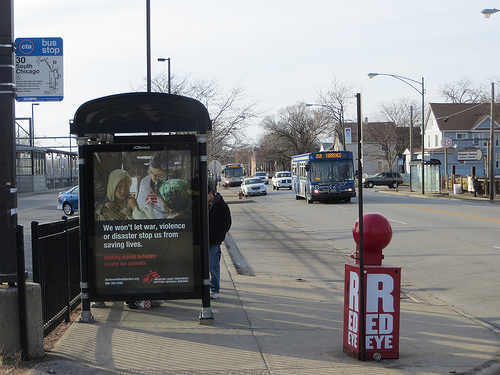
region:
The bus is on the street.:
[278, 135, 415, 240]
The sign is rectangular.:
[9, 27, 70, 114]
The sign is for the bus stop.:
[8, 27, 70, 111]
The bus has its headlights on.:
[284, 130, 374, 217]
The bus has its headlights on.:
[216, 145, 253, 199]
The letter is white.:
[361, 268, 400, 315]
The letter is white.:
[360, 310, 380, 336]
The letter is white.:
[376, 310, 397, 335]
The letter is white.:
[361, 331, 376, 353]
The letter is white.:
[383, 332, 398, 354]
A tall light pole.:
[366, 70, 426, 195]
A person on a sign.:
[96, 165, 133, 216]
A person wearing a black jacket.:
[207, 177, 233, 302]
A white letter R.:
[364, 270, 396, 312]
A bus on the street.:
[289, 148, 358, 206]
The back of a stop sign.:
[208, 155, 225, 192]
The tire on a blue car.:
[61, 199, 74, 216]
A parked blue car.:
[56, 179, 84, 216]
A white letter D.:
[377, 312, 396, 334]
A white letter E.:
[363, 313, 381, 335]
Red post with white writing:
[342, 211, 403, 362]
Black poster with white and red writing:
[74, 133, 214, 303]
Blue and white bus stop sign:
[13, 37, 65, 100]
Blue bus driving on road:
[289, 148, 359, 203]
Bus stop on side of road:
[406, 156, 443, 198]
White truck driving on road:
[270, 168, 292, 192]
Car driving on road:
[239, 176, 269, 198]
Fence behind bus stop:
[27, 206, 83, 340]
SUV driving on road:
[364, 166, 403, 191]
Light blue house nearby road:
[397, 99, 497, 190]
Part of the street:
[418, 240, 460, 282]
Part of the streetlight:
[368, 71, 376, 78]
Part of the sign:
[21, 44, 48, 86]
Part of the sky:
[276, 33, 322, 63]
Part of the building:
[438, 105, 453, 111]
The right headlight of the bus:
[311, 187, 320, 194]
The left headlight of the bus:
[345, 184, 353, 192]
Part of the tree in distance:
[288, 116, 305, 138]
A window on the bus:
[306, 156, 356, 185]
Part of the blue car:
[66, 195, 75, 200]